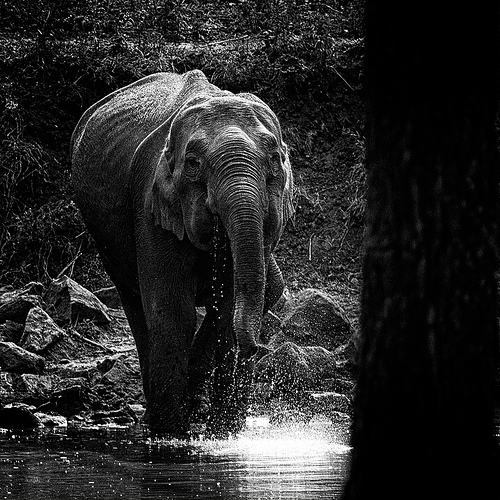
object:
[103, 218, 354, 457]
stream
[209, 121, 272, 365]
trunk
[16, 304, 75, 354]
rock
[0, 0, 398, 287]
trees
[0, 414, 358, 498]
river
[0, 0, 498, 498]
forest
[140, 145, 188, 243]
ear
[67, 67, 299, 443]
elephant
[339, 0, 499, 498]
tree